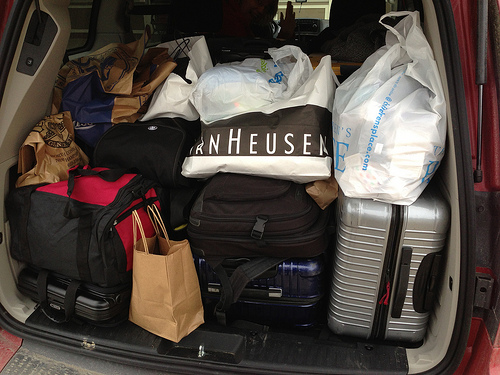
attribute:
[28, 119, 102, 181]
bag — brown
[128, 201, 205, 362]
paper bag — of  paper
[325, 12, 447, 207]
bag — blue, white, plastic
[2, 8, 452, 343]
luggage —  a bunch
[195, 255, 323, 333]
suitcase —  inside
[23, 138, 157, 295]
duffle bag — black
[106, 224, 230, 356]
bag — brown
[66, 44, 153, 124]
bag — paper, crumpled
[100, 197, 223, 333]
bag — brown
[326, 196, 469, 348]
luggage —  bag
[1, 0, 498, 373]
vehicle — back of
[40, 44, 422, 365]
bags — Shopping 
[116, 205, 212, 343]
bags —  a group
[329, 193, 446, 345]
suitcase — Black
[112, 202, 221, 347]
bag — paper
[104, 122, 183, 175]
suitcases — Black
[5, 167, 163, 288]
bag — black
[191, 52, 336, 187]
bag — white 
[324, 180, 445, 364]
suitcase — blue 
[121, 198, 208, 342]
bag — paper, brown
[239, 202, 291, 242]
clip — Black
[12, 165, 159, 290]
duffel bag — red, black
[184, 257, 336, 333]
suitcase — blue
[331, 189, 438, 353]
suitcase — Silver 